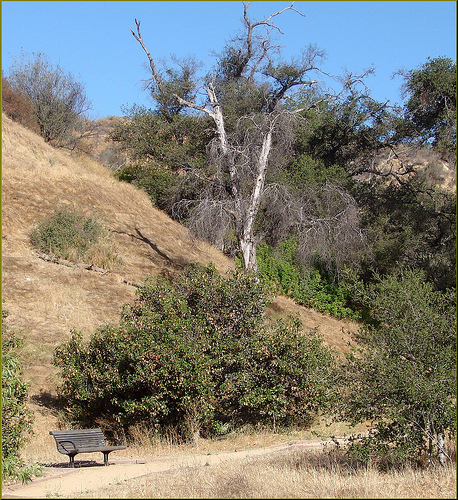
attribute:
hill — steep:
[21, 132, 160, 234]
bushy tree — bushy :
[43, 261, 336, 439]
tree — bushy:
[176, 295, 313, 399]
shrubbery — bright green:
[244, 235, 384, 335]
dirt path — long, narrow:
[4, 423, 403, 498]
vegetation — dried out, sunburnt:
[105, 455, 452, 499]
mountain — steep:
[19, 55, 388, 409]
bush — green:
[53, 257, 346, 443]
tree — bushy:
[341, 158, 431, 210]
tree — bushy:
[7, 42, 105, 157]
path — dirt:
[168, 428, 375, 456]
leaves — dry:
[268, 156, 343, 201]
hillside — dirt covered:
[3, 91, 380, 427]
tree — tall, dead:
[138, 9, 335, 360]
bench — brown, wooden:
[47, 426, 126, 469]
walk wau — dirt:
[41, 421, 427, 492]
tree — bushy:
[121, 36, 368, 293]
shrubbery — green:
[52, 263, 345, 440]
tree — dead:
[172, 82, 333, 288]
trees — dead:
[157, 6, 362, 246]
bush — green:
[103, 172, 297, 493]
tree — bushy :
[30, 204, 126, 274]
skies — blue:
[6, 8, 451, 122]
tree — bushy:
[390, 55, 457, 165]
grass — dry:
[297, 458, 454, 498]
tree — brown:
[121, 30, 370, 323]